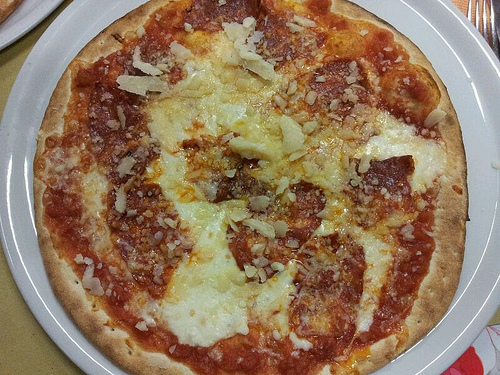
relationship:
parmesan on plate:
[484, 154, 499, 174] [39, 10, 474, 372]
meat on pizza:
[160, 3, 267, 56] [63, 15, 473, 363]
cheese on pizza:
[137, 38, 303, 160] [63, 15, 473, 363]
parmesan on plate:
[491, 159, 500, 170] [39, 10, 474, 372]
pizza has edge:
[63, 15, 473, 363] [40, 233, 137, 371]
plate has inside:
[39, 10, 474, 372] [418, 1, 488, 98]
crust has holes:
[44, 154, 179, 374] [85, 261, 128, 358]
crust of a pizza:
[2, 10, 18, 20] [15, 18, 468, 370]